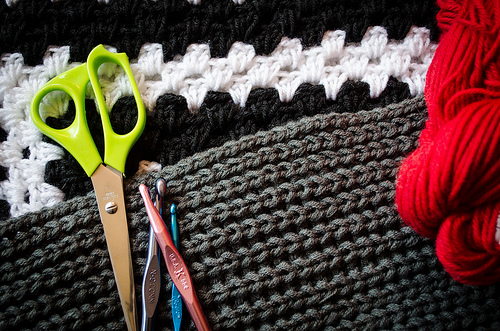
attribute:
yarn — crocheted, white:
[145, 50, 426, 79]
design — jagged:
[7, 44, 439, 103]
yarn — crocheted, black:
[3, 5, 430, 23]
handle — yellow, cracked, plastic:
[27, 42, 149, 177]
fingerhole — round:
[32, 86, 77, 132]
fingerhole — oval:
[92, 54, 140, 137]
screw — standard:
[104, 199, 120, 216]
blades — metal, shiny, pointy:
[91, 162, 139, 331]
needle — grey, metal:
[141, 181, 203, 330]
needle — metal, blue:
[165, 200, 188, 326]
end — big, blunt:
[136, 182, 165, 233]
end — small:
[164, 199, 178, 222]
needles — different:
[133, 175, 218, 331]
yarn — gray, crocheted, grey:
[5, 99, 461, 327]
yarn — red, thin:
[393, 1, 499, 277]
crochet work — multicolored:
[4, 2, 407, 98]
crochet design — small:
[215, 152, 338, 186]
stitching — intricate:
[157, 56, 229, 94]